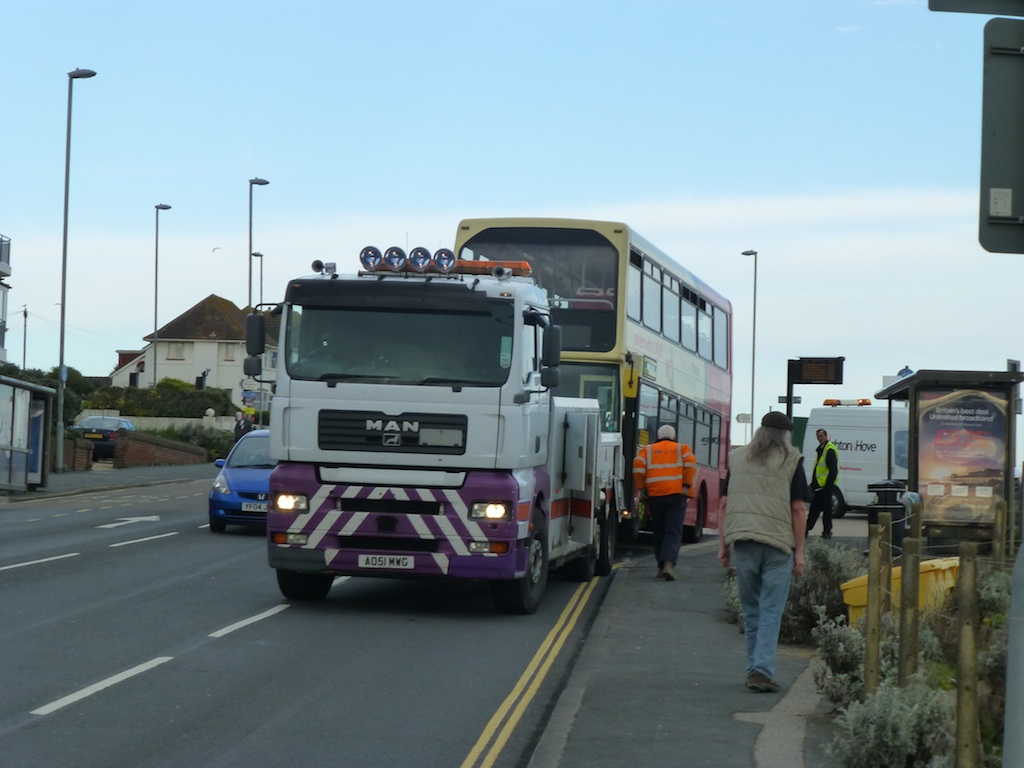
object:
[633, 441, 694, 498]
jacket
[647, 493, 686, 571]
pants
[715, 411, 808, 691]
man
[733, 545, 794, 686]
jeans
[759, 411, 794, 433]
cap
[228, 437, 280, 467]
window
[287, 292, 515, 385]
window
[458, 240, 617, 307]
window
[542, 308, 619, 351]
window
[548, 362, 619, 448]
window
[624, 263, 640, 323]
window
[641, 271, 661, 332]
window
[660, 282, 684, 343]
window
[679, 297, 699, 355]
window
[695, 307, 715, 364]
window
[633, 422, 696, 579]
man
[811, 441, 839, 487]
vest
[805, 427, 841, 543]
man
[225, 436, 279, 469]
windshield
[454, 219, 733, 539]
bus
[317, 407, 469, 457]
grill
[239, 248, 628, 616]
bus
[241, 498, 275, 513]
license plate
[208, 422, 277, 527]
car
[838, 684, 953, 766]
shrub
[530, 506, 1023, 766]
ground